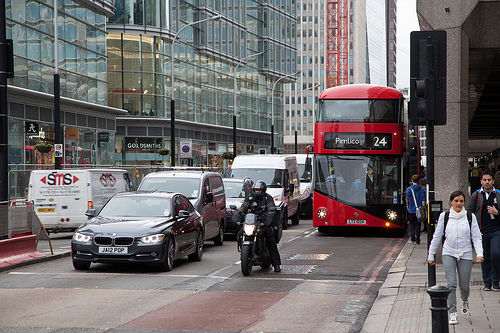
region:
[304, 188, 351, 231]
light on front of bus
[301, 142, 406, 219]
window on front of bus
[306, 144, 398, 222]
reflection in the window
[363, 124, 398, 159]
number on the bus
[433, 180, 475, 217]
head of the lady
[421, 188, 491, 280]
lady wearing white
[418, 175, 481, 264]
lady on the sidewalk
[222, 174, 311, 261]
person on a bike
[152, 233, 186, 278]
tire of the car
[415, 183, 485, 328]
person wearing a back pack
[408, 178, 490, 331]
person wearing a white jacket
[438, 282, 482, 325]
a pair of sneakers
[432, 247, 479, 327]
a pair of jeans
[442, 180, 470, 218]
head of a person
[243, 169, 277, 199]
a motorcycle helmet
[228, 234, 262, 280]
front wheel of a motorcycle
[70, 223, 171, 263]
front headlights of a car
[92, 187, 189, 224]
windshield of a car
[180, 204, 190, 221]
side view mirror of a car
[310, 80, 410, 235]
a red double decker bus on a London street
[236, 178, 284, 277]
rider on a black motorcycle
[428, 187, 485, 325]
woman wears a white jacket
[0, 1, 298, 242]
tall building with many glass windows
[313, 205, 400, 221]
headlights on the bus are on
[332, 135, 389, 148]
destination and bus number displayed on the front of a bus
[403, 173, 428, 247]
guy in a blue hoodie wears a cross shoulder bag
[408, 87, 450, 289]
traffic lights on a black pole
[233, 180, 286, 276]
motorcyclist wears a black crash helmet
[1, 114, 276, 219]
store fronts along a busy street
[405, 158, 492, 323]
people walking along side walk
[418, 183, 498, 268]
lady wearing white jacket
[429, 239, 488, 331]
lady wearing grey pants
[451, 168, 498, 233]
man wearing black shirt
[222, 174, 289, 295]
man on motorcycle at traffic light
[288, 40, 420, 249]
red double decker bus parked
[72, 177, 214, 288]
bmw parked at traffic light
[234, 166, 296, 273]
man dressed in black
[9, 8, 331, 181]
glass building across the street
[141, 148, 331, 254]
row of cars parked at traffic light